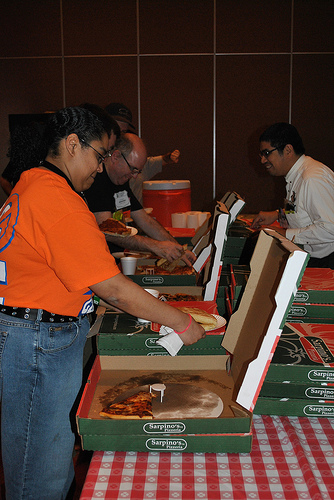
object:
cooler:
[139, 177, 192, 229]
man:
[251, 124, 334, 264]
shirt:
[280, 153, 333, 260]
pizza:
[180, 306, 216, 331]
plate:
[163, 312, 228, 332]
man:
[85, 130, 199, 268]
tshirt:
[87, 166, 145, 215]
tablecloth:
[77, 415, 332, 499]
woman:
[0, 102, 208, 500]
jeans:
[0, 314, 89, 499]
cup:
[121, 256, 138, 275]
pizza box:
[262, 322, 334, 384]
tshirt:
[0, 168, 122, 320]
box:
[75, 224, 310, 436]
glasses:
[259, 146, 283, 158]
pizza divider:
[149, 382, 167, 403]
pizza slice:
[97, 388, 152, 420]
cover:
[218, 228, 310, 413]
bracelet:
[174, 313, 192, 334]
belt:
[1, 304, 78, 325]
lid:
[142, 179, 191, 190]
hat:
[102, 100, 138, 130]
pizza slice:
[95, 215, 132, 236]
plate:
[102, 225, 139, 239]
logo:
[141, 421, 187, 435]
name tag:
[113, 190, 133, 211]